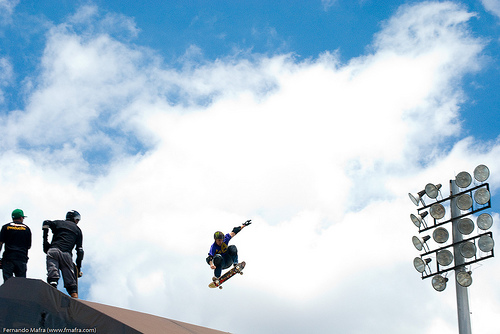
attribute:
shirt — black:
[3, 218, 37, 265]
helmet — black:
[62, 205, 84, 220]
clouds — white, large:
[200, 76, 337, 173]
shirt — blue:
[208, 234, 235, 260]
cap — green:
[10, 205, 25, 220]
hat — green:
[12, 210, 25, 219]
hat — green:
[6, 202, 28, 219]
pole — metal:
[441, 170, 476, 332]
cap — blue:
[5, 195, 38, 222]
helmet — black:
[64, 204, 78, 219]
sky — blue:
[4, 3, 496, 333]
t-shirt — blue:
[206, 241, 238, 266]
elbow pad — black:
[227, 225, 243, 235]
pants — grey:
[0, 242, 82, 299]